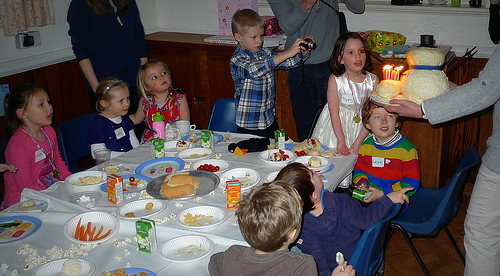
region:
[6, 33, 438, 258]
Children are having party.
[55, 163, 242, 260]
Table cloth is white cloth.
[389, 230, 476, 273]
Floor is brown color.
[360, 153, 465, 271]
Chair is blue color.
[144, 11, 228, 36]
Wall is white color.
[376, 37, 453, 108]
Cake is white color.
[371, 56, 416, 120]
candles are on.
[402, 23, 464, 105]
Cake is snow man shape.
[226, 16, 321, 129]
Boy is taking picture.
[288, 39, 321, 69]
Camera is black color.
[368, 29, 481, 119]
A SNOWMAN BIRTHDAY CAKE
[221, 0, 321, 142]
A LITTLE BOY TAKING A PICTURE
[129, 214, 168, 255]
A JUICE BOX ON THE TABLE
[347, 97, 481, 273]
A BOY SITTING ON A BLUE CHAIR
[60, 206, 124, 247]
CARROT SLICES ON A PAPER PLATE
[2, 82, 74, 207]
A LITTLE GIRL WEARING PINK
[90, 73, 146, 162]
A LITTLE GIRL WEARING A HEAD BAND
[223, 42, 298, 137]
A LITTLE BOYS PLAID SHIRT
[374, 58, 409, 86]
LIT BIRTHDAY CANDLES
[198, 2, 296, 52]
BIRTHDAY PRESENTS ON THE COUNTER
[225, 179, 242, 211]
small orange juice box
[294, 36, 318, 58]
small black camera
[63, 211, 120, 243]
thin-cut carrot strips in a paper bowl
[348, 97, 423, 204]
boy clad in multi-color sweater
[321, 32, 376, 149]
girl in white sleeveless dress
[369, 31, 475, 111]
snowman-style cake with lit candles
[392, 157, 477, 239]
blue plasic chair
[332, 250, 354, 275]
plastic spoon in boy's hand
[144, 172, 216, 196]
pancakes on a "silver" platter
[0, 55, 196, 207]
three girls partygoers on the left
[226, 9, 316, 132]
Child taking photograph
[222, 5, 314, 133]
Child holding small black camera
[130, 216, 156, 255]
Green juice box on table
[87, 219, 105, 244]
Carrot slice in white plate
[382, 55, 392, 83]
Candle is lit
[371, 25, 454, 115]
White snowman cake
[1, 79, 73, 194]
Young girl wearing pink top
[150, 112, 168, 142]
Bottle is pink with green top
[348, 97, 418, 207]
Child sitting on blue chair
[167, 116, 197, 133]
White mug by pink bottle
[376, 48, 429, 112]
a cake with candles on fire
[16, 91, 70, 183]
a girl with a pink shirt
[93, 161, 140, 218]
a juice box on the table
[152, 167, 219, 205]
hot dog buns on a plate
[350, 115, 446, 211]
a boy wearing a colorful shirt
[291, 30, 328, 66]
a boy holding a camera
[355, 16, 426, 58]
a gift wrapped package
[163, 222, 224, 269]
a paper plate sitting on a table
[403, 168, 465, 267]
a blue chair in the room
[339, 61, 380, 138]
a girl wearing a necklace